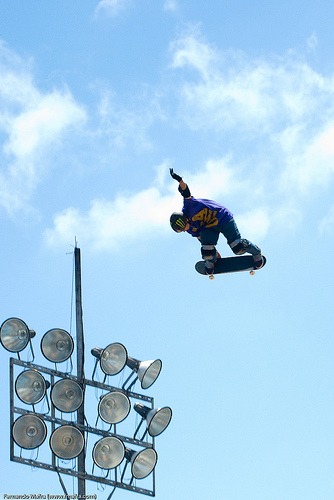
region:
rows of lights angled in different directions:
[3, 304, 170, 493]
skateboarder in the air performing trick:
[154, 130, 268, 286]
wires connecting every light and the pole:
[4, 233, 156, 493]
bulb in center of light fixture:
[6, 400, 48, 456]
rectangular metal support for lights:
[2, 341, 151, 494]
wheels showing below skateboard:
[191, 248, 270, 277]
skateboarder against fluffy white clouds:
[153, 162, 273, 287]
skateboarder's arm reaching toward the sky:
[148, 152, 273, 275]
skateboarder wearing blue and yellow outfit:
[156, 184, 275, 280]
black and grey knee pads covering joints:
[191, 234, 264, 266]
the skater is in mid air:
[161, 164, 269, 279]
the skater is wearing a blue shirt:
[175, 184, 235, 236]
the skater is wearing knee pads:
[197, 238, 252, 260]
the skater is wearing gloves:
[169, 166, 184, 181]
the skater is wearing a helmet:
[169, 210, 188, 233]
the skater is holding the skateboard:
[196, 247, 268, 278]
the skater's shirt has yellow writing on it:
[180, 196, 232, 234]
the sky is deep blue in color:
[2, 1, 330, 497]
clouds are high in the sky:
[2, 6, 329, 272]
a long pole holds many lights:
[69, 245, 90, 497]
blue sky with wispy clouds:
[0, 1, 330, 290]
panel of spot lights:
[0, 312, 179, 497]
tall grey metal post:
[65, 242, 100, 496]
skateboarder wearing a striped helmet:
[158, 158, 267, 285]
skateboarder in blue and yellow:
[157, 161, 273, 278]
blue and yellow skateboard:
[193, 250, 273, 277]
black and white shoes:
[196, 246, 273, 271]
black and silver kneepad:
[199, 241, 216, 261]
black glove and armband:
[165, 165, 191, 197]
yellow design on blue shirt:
[189, 202, 221, 229]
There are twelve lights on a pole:
[4, 317, 172, 472]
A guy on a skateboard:
[161, 162, 269, 290]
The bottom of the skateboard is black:
[182, 252, 277, 279]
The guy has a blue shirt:
[176, 192, 233, 249]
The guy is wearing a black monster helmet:
[170, 208, 195, 243]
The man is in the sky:
[5, 132, 333, 309]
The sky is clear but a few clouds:
[3, 72, 332, 188]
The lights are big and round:
[2, 318, 161, 475]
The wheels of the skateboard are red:
[199, 271, 264, 277]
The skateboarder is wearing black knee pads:
[194, 243, 269, 270]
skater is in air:
[160, 163, 271, 279]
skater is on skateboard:
[193, 246, 266, 282]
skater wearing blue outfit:
[178, 195, 263, 261]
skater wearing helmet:
[168, 209, 189, 233]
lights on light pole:
[1, 313, 176, 496]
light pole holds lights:
[70, 246, 90, 495]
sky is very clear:
[0, 0, 332, 498]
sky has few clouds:
[0, 0, 333, 499]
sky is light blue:
[1, 0, 333, 499]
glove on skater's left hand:
[169, 167, 183, 183]